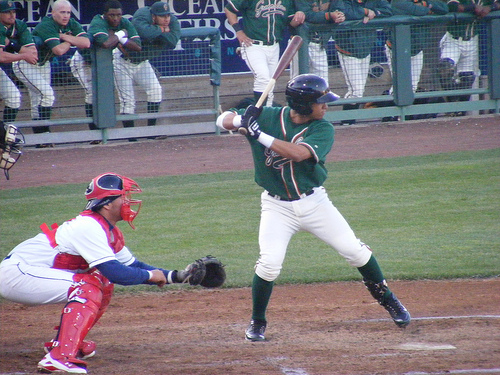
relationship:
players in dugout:
[18, 2, 499, 139] [16, 0, 415, 149]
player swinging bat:
[220, 66, 405, 317] [230, 23, 307, 146]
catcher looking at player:
[22, 151, 217, 367] [211, 70, 414, 343]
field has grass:
[8, 81, 500, 358] [6, 169, 491, 286]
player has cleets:
[220, 66, 405, 317] [243, 282, 427, 350]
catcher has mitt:
[22, 151, 217, 367] [170, 246, 249, 299]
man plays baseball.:
[220, 66, 405, 317] [195, 29, 406, 268]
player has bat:
[220, 66, 405, 317] [230, 23, 307, 146]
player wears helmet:
[220, 66, 405, 317] [277, 72, 348, 114]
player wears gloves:
[220, 66, 405, 317] [231, 108, 276, 151]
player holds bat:
[220, 66, 405, 317] [230, 23, 307, 146]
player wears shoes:
[220, 66, 405, 317] [239, 295, 443, 358]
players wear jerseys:
[18, 2, 499, 139] [1, 6, 477, 40]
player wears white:
[1, 162, 179, 351] [4, 195, 134, 312]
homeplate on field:
[200, 217, 480, 374] [8, 81, 500, 358]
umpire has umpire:
[2, 114, 31, 177] [0, 120, 27, 182]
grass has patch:
[6, 169, 491, 286] [31, 134, 500, 291]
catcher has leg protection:
[22, 151, 217, 367] [50, 262, 125, 374]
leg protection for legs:
[50, 262, 125, 374] [4, 225, 111, 322]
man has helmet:
[220, 66, 405, 317] [72, 158, 150, 234]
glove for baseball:
[170, 246, 249, 299] [238, 19, 312, 163]